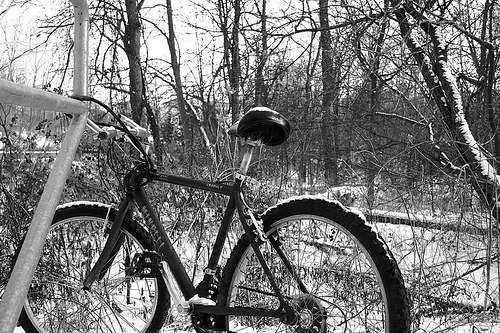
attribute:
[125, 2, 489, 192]
trees — bare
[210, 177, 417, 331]
tire — snow covered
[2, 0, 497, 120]
sky — background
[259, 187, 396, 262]
tire — black 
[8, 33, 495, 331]
photo — black, white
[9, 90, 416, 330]
bike — leaning, black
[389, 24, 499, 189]
branch — snow covered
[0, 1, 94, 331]
pole — silver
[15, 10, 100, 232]
bar — grey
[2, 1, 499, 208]
trees — distant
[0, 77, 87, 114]
pole — metal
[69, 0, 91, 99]
pole — metal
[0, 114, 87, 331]
pole — metal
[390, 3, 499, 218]
branch — snow covered, tree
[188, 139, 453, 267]
trunk — tree, fallen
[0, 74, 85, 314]
pole — metal